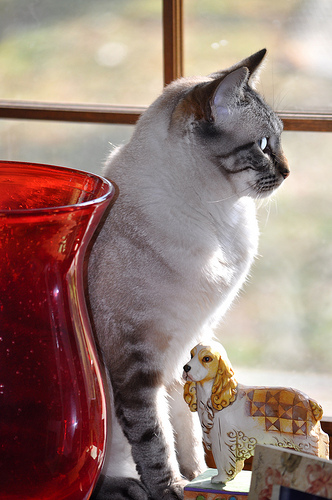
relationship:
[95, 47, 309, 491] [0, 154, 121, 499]
cat near vase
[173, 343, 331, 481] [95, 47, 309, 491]
toy under cat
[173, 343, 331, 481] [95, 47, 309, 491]
toy below cat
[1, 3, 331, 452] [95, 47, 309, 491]
window near cat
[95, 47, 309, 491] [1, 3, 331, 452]
cat near window